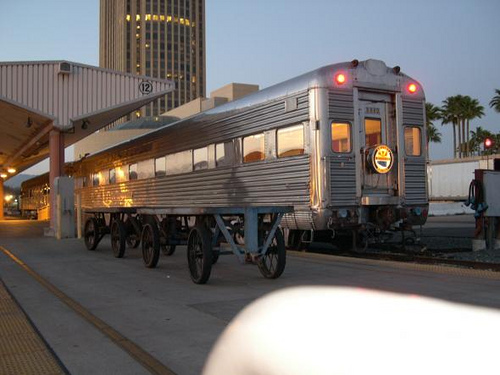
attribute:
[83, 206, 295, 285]
cart — metal, light blue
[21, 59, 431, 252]
train — silver, stopped, empty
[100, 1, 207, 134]
building — tall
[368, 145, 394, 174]
object — round, lit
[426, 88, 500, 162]
trees — tall, palm trees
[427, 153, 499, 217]
wall — white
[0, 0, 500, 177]
sky — dark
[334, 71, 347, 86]
tail light — red, bright red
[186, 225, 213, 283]
wheel — black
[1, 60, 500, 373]
train station — empty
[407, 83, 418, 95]
tail light — red